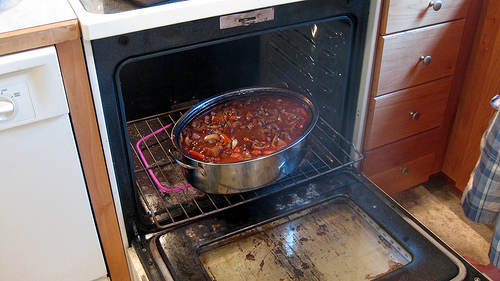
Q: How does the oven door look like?
A: Dirty.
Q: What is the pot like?
A: Silver.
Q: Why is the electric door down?
A: The door is open.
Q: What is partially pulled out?
A: A grate.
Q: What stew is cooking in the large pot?
A: Beef stew.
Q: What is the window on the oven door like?
A: Greasy.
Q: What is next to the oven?
A: The dishwasher.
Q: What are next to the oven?
A: Drawers.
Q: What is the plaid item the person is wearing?
A: A shirt.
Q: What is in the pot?
A: Stew.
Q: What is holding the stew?
A: Silver pot.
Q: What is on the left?
A: Dishwasher.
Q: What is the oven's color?
A: Black and white.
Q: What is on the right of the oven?
A: Drawers.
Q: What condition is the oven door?
A: Dirty.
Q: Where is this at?
A: A kitchen.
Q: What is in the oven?
A: A dish.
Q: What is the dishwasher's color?
A: White.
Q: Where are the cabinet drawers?
A: Next to the oven.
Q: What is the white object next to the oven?
A: A dishwasher.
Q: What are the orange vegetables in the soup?
A: Carrots.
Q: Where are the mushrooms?
A: In the soup.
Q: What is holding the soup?
A: A silver pot.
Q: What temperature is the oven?
A: 350 degrees.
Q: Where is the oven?
A: In the stove.